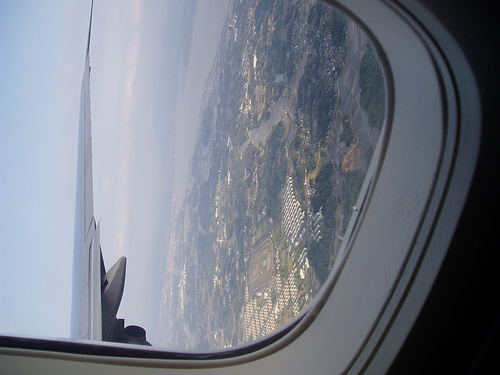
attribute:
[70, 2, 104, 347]
wing — thin, white, narrow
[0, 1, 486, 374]
window — white, small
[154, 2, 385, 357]
ground — upright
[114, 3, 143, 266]
cloud — white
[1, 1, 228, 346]
sky — clear, hazy, cloudy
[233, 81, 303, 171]
river — meandering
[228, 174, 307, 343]
structures — white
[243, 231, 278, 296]
form — rectangular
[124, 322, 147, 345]
cylinder — white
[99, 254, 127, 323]
protrusion — pointy